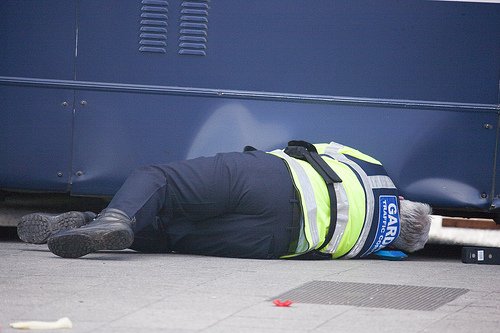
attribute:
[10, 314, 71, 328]
glove — latex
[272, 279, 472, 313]
vent — grated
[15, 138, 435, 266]
man — checking, wearing, laying, lying, looking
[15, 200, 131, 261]
shoe — black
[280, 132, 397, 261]
vest — green, blue, gray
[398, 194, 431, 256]
hair — white, grey, gray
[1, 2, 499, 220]
train — blue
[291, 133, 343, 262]
belt — black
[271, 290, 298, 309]
trash — red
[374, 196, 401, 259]
word — traffic control, white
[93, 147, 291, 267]
pant — blue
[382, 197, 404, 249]
sign — blue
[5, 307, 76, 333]
paper — white